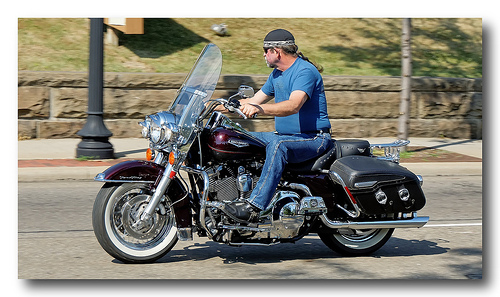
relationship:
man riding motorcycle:
[223, 26, 329, 218] [93, 37, 422, 259]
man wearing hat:
[223, 26, 329, 218] [260, 29, 304, 48]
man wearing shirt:
[223, 26, 329, 218] [259, 69, 344, 137]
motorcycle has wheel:
[93, 37, 422, 259] [97, 170, 186, 264]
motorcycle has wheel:
[93, 37, 422, 259] [326, 190, 399, 257]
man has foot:
[223, 26, 329, 218] [224, 192, 263, 220]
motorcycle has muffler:
[93, 37, 422, 259] [320, 200, 440, 234]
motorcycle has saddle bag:
[93, 37, 422, 259] [335, 163, 422, 212]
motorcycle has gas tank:
[93, 37, 422, 259] [215, 125, 262, 155]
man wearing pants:
[223, 26, 329, 218] [249, 129, 332, 204]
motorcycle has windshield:
[93, 37, 422, 259] [164, 45, 225, 137]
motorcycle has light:
[93, 37, 422, 259] [150, 112, 166, 144]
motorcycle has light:
[93, 37, 422, 259] [167, 127, 180, 142]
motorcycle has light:
[93, 37, 422, 259] [137, 114, 153, 132]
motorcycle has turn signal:
[93, 37, 422, 259] [165, 152, 187, 171]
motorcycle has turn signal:
[93, 37, 422, 259] [139, 142, 158, 160]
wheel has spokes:
[97, 170, 186, 264] [118, 199, 164, 237]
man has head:
[223, 26, 329, 218] [258, 29, 305, 70]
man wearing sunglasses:
[223, 26, 329, 218] [263, 46, 276, 57]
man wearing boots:
[223, 26, 329, 218] [225, 197, 261, 217]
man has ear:
[223, 26, 329, 218] [275, 46, 284, 60]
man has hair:
[223, 26, 329, 218] [291, 46, 327, 73]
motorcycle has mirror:
[93, 37, 422, 259] [236, 80, 258, 104]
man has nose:
[223, 26, 329, 218] [262, 51, 273, 60]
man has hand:
[223, 26, 329, 218] [239, 107, 265, 122]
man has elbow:
[223, 26, 329, 218] [281, 91, 306, 120]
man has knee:
[223, 26, 329, 218] [264, 135, 303, 169]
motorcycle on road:
[93, 37, 422, 259] [32, 173, 475, 277]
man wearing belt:
[223, 26, 329, 218] [301, 127, 337, 136]